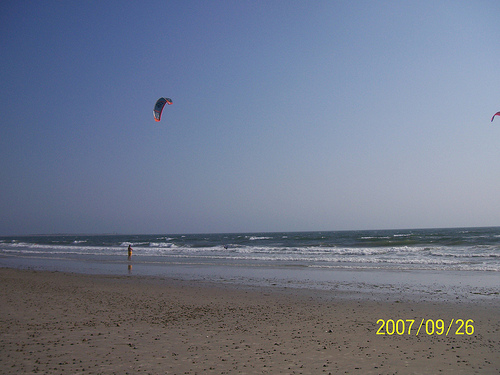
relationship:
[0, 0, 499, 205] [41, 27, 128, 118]
cloud in blue sky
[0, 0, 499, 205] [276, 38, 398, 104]
cloud in sky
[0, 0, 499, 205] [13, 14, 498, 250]
cloud in sky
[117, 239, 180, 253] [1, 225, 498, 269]
wave in ocean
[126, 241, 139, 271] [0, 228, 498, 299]
person standing in water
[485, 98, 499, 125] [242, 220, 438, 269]
parachute over water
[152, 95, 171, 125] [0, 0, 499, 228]
kite in sky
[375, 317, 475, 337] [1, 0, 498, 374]
date stamp in photo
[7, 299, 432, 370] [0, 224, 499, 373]
footprints are in beach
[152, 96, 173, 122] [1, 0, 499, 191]
kite in air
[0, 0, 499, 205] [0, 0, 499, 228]
cloud in sky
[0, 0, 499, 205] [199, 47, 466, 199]
cloud in sky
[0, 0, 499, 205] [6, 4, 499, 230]
cloud in blue sky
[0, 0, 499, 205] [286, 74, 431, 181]
cloud in sky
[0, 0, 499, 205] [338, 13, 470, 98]
cloud in sky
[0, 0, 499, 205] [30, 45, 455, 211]
cloud in sky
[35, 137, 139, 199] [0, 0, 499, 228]
cloud in sky